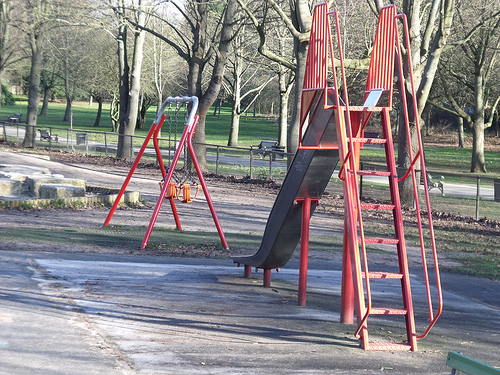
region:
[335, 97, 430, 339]
red ladder with six rungs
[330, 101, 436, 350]
red metal ladder on a playground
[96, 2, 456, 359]
public playground in a park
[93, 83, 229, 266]
two swings for children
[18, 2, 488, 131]
many trees with all their leaves gone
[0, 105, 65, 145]
two empty park benches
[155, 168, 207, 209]
two orange swings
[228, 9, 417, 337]
metal slide in a playground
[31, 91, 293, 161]
empty park area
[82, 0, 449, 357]
empty playground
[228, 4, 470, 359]
a metal and red slide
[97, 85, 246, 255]
a red, grey, and orange swingset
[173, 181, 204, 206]
an orange swing seat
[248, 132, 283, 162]
an empty park bench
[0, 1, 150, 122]
brown trees without and leaves on green grass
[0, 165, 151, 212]
a grey stone structure on a playground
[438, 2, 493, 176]
a brown tree with no leaves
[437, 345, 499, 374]
the green top of a park bench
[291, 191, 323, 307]
a red metal support pole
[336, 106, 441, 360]
a red ladder to the top of a slide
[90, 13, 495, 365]
a park with red playground equipment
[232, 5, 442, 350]
a silver slide is in the playground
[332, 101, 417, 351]
the slide has red stairs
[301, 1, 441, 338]
the slide has red rails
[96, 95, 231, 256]
the swing has two yellow baby seats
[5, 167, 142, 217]
the park has stone carvings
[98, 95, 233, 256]
green grass is beneath the swings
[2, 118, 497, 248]
a fence surrounds the park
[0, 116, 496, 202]
benches line the walkway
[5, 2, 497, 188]
the trees are bare in the park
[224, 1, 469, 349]
tall red sliding board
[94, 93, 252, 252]
small red swing set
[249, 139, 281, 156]
bench sitting in the park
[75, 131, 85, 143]
waste basket sitting in the park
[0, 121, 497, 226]
metal fence behind the bench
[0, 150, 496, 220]
pile of leaves near the fence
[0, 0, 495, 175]
large trees in the park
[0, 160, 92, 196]
pile of rocks in middle of park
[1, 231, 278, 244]
astro turf under swing set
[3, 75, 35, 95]
small building in the background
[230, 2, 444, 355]
Red slide in a playground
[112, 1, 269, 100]
Trees with no leaves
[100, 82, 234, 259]
Red swing set in a playground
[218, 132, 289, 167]
Park bench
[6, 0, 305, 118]
Bare trees lining a path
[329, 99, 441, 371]
Ladder on a slide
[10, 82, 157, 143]
Grass field in a park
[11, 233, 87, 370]
Bare ground in a children's park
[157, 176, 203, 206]
Orange swings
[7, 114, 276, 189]
Path along a public park